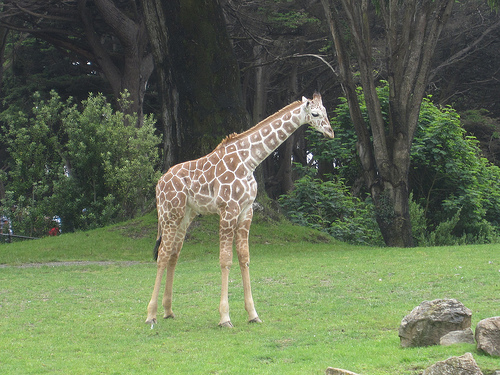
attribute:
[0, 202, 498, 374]
grass — green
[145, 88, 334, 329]
giraffe — young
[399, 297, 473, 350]
rock — large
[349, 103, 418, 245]
tree trunk — large, brown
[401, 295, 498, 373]
rocks — large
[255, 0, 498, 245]
trees — small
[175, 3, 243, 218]
moss — growing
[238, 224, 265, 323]
leg — four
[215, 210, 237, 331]
leg — four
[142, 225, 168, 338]
leg — four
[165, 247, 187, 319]
leg — four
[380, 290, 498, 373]
stones — large, gray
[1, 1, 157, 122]
tree — small grouping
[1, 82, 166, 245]
tree — small grouping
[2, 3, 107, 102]
tree — small grouping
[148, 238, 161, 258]
hair — black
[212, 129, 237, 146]
brown mane — short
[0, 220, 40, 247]
fence — wooden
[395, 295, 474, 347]
rock — large, gray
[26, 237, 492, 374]
grass — big area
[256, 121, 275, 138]
spot — brown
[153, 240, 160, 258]
hair — black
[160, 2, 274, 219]
tree trunk — large, mossy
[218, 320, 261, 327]
hooves — black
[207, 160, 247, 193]
spot — brown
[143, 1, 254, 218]
tree trunk — thick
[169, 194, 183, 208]
spot — brown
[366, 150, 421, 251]
bark — dark gray